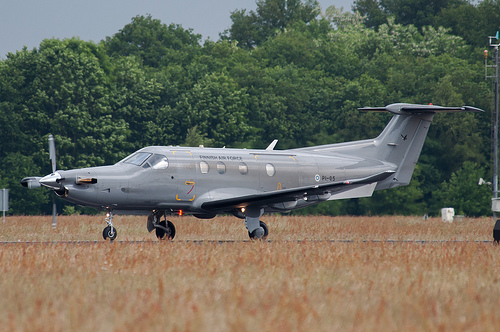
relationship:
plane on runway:
[26, 107, 425, 218] [37, 200, 480, 284]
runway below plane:
[37, 200, 480, 284] [26, 107, 425, 218]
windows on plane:
[125, 149, 189, 179] [26, 107, 425, 218]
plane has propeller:
[26, 107, 425, 218] [33, 134, 83, 207]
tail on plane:
[373, 87, 493, 172] [26, 107, 425, 218]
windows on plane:
[122, 149, 170, 173] [26, 107, 425, 218]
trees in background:
[100, 17, 490, 103] [40, 31, 466, 168]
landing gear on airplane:
[106, 200, 289, 246] [26, 107, 425, 218]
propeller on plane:
[39, 166, 62, 191] [26, 107, 425, 218]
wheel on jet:
[229, 218, 281, 251] [26, 107, 425, 218]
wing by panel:
[195, 171, 373, 229] [167, 157, 287, 185]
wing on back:
[195, 171, 373, 229] [295, 150, 427, 233]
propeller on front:
[39, 166, 62, 191] [23, 152, 180, 236]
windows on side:
[125, 149, 189, 179] [152, 139, 358, 180]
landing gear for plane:
[106, 200, 289, 246] [26, 107, 425, 218]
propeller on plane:
[33, 134, 83, 207] [26, 107, 425, 218]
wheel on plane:
[229, 218, 281, 251] [26, 107, 425, 218]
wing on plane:
[195, 171, 373, 229] [26, 107, 425, 218]